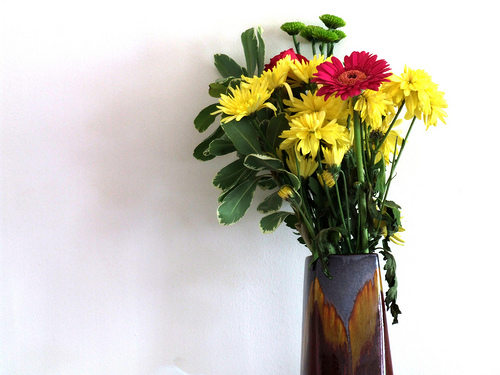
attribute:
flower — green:
[280, 20, 303, 47]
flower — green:
[301, 24, 325, 52]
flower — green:
[319, 12, 346, 28]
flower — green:
[321, 26, 344, 46]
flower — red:
[266, 50, 310, 68]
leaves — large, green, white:
[204, 26, 269, 110]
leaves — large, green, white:
[189, 101, 286, 173]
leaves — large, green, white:
[247, 154, 316, 233]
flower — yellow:
[216, 67, 276, 119]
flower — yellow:
[283, 110, 344, 156]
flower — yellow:
[353, 88, 400, 133]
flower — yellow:
[289, 54, 325, 82]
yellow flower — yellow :
[216, 54, 299, 121]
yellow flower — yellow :
[277, 93, 347, 174]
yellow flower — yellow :
[356, 89, 394, 132]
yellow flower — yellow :
[383, 65, 448, 126]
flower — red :
[315, 51, 391, 96]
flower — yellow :
[282, 90, 349, 176]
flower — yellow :
[395, 66, 446, 121]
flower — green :
[279, 21, 303, 51]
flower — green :
[298, 24, 335, 54]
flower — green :
[320, 12, 346, 55]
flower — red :
[266, 45, 308, 68]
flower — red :
[310, 50, 390, 97]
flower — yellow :
[214, 55, 294, 121]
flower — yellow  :
[279, 110, 349, 175]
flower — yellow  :
[381, 64, 447, 126]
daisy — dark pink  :
[309, 50, 390, 98]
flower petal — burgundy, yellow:
[305, 273, 349, 373]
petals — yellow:
[389, 71, 409, 89]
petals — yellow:
[418, 90, 432, 117]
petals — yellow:
[429, 88, 447, 125]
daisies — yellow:
[216, 53, 330, 123]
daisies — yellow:
[278, 85, 354, 185]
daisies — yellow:
[356, 66, 445, 142]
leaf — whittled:
[381, 216, 402, 323]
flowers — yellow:
[276, 183, 295, 202]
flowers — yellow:
[315, 164, 341, 186]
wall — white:
[1, 2, 301, 372]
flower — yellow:
[386, 66, 447, 126]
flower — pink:
[308, 49, 394, 100]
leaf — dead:
[375, 241, 412, 325]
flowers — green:
[279, 6, 352, 48]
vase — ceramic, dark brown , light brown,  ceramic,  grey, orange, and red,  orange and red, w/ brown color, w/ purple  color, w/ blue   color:
[304, 250, 391, 372]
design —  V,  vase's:
[311, 272, 381, 370]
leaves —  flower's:
[382, 245, 402, 324]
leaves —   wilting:
[381, 242, 401, 322]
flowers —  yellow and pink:
[207, 50, 446, 251]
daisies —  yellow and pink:
[211, 49, 449, 249]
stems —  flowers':
[292, 186, 378, 251]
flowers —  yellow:
[278, 92, 448, 251]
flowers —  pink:
[310, 50, 394, 106]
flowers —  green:
[279, 11, 345, 45]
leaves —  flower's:
[194, 111, 307, 228]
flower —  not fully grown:
[275, 185, 294, 195]